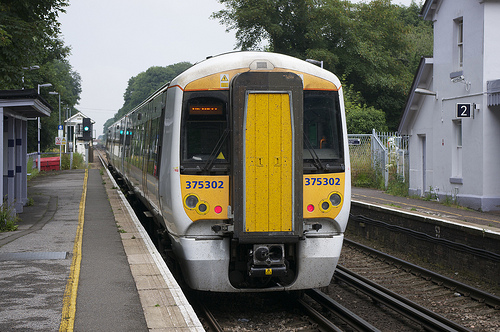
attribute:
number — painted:
[189, 178, 199, 190]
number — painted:
[215, 178, 224, 190]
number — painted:
[200, 178, 211, 190]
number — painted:
[302, 173, 310, 186]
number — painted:
[326, 175, 335, 186]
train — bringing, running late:
[106, 48, 350, 294]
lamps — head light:
[188, 199, 380, 256]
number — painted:
[208, 177, 216, 192]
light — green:
[81, 118, 91, 138]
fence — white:
[349, 134, 409, 185]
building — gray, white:
[397, 1, 499, 211]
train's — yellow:
[102, 0, 354, 262]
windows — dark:
[165, 83, 327, 195]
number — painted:
[178, 179, 222, 191]